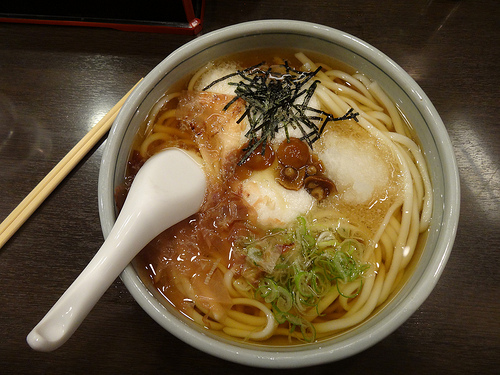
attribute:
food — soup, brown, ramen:
[127, 48, 435, 339]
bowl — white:
[96, 15, 464, 374]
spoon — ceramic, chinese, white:
[28, 146, 207, 351]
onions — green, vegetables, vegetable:
[252, 214, 366, 336]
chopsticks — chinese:
[0, 73, 149, 244]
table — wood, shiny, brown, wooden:
[1, 1, 498, 374]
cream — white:
[319, 129, 388, 207]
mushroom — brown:
[275, 138, 313, 167]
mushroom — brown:
[273, 161, 308, 190]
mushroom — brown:
[303, 171, 338, 200]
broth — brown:
[138, 250, 164, 265]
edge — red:
[0, 16, 198, 36]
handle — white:
[25, 226, 138, 352]